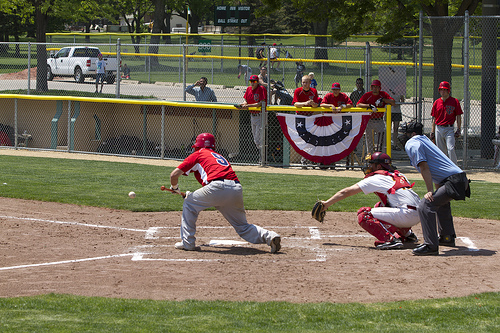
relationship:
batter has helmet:
[169, 131, 284, 256] [196, 129, 217, 151]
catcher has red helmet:
[317, 152, 424, 250] [355, 144, 397, 175]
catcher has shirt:
[317, 152, 424, 250] [349, 171, 427, 213]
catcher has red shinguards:
[311, 152, 421, 249] [355, 206, 399, 244]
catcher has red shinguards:
[311, 152, 421, 249] [374, 201, 383, 206]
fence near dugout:
[1, 10, 499, 168] [0, 93, 386, 165]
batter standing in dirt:
[169, 131, 284, 256] [0, 194, 499, 310]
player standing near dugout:
[239, 75, 269, 110] [4, 81, 412, 171]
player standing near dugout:
[286, 70, 316, 100] [4, 81, 412, 171]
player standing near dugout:
[422, 80, 464, 163] [4, 81, 412, 171]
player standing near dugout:
[358, 73, 391, 128] [4, 81, 412, 171]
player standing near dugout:
[322, 72, 358, 117] [4, 81, 412, 171]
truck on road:
[46, 42, 123, 85] [1, 69, 498, 134]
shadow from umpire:
[447, 239, 489, 261] [399, 112, 471, 263]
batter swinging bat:
[169, 131, 284, 256] [152, 177, 205, 202]